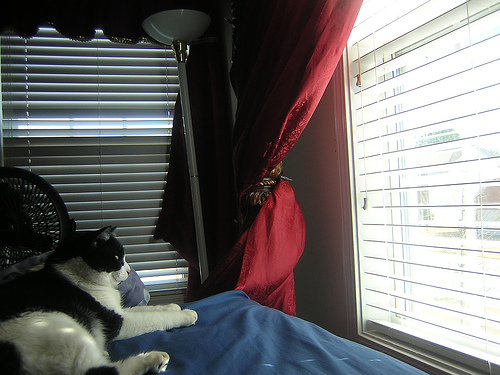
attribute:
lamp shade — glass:
[140, 5, 210, 45]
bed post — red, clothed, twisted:
[195, 0, 362, 315]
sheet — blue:
[99, 286, 434, 373]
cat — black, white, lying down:
[1, 225, 198, 373]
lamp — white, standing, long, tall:
[144, 9, 210, 281]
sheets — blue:
[107, 285, 437, 374]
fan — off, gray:
[6, 165, 72, 255]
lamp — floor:
[140, 3, 235, 292]